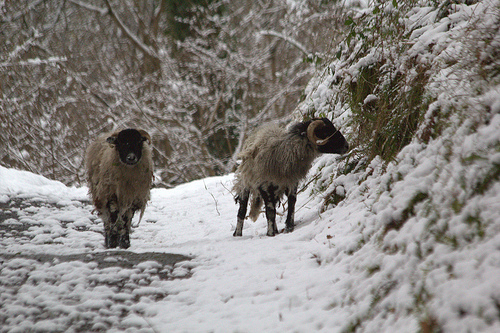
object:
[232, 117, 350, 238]
sheep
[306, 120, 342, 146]
horns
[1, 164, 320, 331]
ground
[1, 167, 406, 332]
snow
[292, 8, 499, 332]
hill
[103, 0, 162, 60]
branches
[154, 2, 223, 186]
trees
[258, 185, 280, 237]
legs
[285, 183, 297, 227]
ram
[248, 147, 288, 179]
fur